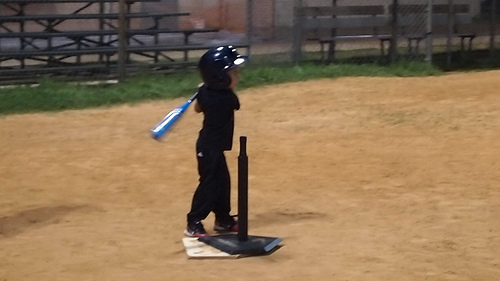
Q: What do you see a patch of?
A: Grass.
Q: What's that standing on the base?
A: T-ball.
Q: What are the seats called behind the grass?
A: Bleachers.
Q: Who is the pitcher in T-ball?
A: Tee.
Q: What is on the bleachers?
A: Empty.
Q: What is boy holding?
A: Bat.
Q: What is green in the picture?
A: Grass.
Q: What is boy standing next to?
A: Base.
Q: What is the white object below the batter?
A: Home plate.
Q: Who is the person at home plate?
A: The batter.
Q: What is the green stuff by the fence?
A: Grass.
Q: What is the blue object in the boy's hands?
A: A bat.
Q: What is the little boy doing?
A: Playing t ball.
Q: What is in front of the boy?
A: A t ball stand.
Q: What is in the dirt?
A: Footprints.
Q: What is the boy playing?
A: He is playing t ball.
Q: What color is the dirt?
A: Brown.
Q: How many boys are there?
A: One.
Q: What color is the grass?
A: Green.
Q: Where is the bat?
A: In the boy's hands.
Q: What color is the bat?
A: Blue.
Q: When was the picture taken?
A: Daytime.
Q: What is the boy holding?
A: A bat.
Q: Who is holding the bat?
A: The boy.